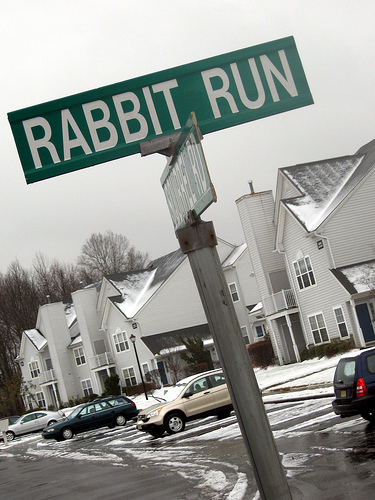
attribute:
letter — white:
[20, 112, 62, 172]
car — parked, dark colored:
[40, 395, 139, 441]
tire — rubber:
[60, 427, 77, 438]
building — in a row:
[227, 138, 374, 368]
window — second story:
[288, 253, 318, 293]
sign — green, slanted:
[5, 35, 316, 186]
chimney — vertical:
[244, 178, 259, 194]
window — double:
[303, 312, 332, 346]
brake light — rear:
[353, 377, 370, 400]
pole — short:
[132, 340, 149, 406]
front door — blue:
[353, 301, 374, 348]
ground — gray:
[3, 346, 374, 498]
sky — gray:
[3, 3, 372, 277]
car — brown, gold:
[135, 363, 235, 440]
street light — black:
[125, 333, 152, 403]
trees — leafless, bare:
[75, 229, 152, 285]